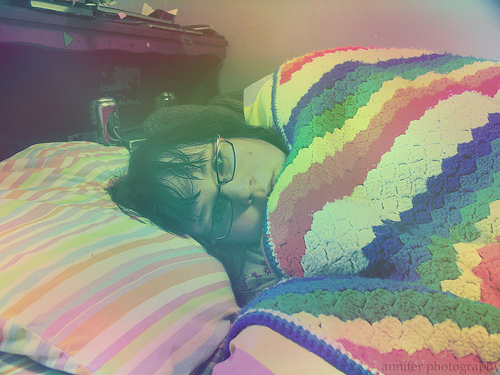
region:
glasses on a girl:
[197, 133, 244, 253]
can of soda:
[82, 95, 129, 147]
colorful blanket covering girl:
[291, 69, 477, 324]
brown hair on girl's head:
[133, 104, 200, 234]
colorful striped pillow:
[8, 158, 103, 349]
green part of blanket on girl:
[315, 102, 350, 119]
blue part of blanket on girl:
[390, 215, 411, 232]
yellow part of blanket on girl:
[401, 320, 457, 340]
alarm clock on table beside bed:
[121, 125, 141, 146]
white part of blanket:
[406, 143, 424, 174]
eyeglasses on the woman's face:
[208, 135, 235, 248]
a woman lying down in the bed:
[5, 45, 496, 370]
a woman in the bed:
[1, 1, 496, 372]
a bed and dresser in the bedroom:
[2, 2, 499, 374]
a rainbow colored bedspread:
[215, 45, 498, 374]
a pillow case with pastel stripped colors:
[0, 140, 235, 374]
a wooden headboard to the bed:
[2, 2, 228, 140]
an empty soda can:
[92, 97, 122, 146]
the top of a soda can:
[151, 90, 178, 102]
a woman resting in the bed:
[2, 47, 493, 371]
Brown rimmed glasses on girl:
[210, 137, 239, 242]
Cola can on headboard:
[86, 91, 128, 147]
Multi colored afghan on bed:
[337, 132, 459, 272]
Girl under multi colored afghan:
[132, 99, 448, 241]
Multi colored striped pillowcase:
[34, 241, 163, 318]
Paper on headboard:
[132, 3, 190, 19]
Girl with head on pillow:
[110, 93, 282, 254]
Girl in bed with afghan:
[81, 90, 491, 265]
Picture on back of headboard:
[96, 60, 143, 112]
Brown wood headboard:
[1, 3, 233, 110]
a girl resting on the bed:
[10, 25, 492, 354]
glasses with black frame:
[210, 137, 239, 244]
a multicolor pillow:
[3, 144, 185, 371]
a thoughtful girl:
[121, 78, 355, 339]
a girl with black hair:
[117, 103, 281, 249]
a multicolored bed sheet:
[286, 61, 494, 365]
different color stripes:
[20, 240, 240, 340]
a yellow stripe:
[311, 318, 498, 348]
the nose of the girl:
[224, 179, 264, 206]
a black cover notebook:
[27, 1, 104, 21]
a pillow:
[23, 196, 145, 328]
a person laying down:
[114, 136, 498, 338]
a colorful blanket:
[286, 114, 498, 310]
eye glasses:
[188, 144, 246, 242]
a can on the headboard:
[82, 100, 133, 145]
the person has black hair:
[122, 160, 187, 207]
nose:
[232, 176, 257, 203]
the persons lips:
[260, 171, 276, 201]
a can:
[150, 85, 176, 108]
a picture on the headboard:
[91, 69, 155, 102]